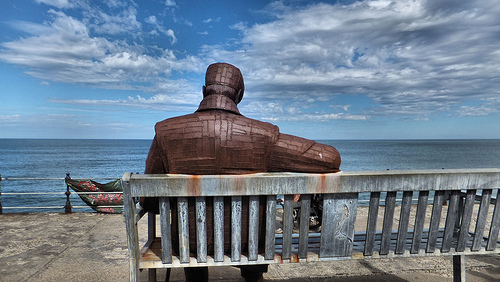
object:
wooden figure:
[141, 61, 344, 282]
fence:
[0, 172, 125, 215]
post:
[62, 170, 73, 214]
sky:
[0, 0, 499, 140]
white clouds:
[0, 0, 499, 141]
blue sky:
[0, 0, 499, 140]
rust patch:
[187, 174, 202, 196]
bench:
[122, 168, 500, 281]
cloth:
[64, 175, 123, 213]